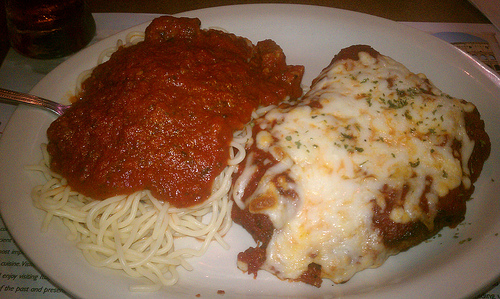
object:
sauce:
[39, 11, 310, 208]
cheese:
[242, 48, 480, 287]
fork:
[3, 87, 71, 113]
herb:
[287, 76, 446, 173]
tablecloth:
[395, 21, 500, 77]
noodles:
[24, 25, 289, 290]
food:
[32, 15, 489, 285]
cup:
[0, 2, 96, 60]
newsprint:
[2, 234, 60, 298]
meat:
[150, 9, 285, 66]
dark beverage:
[2, 4, 97, 60]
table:
[0, 0, 499, 296]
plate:
[0, 3, 498, 297]